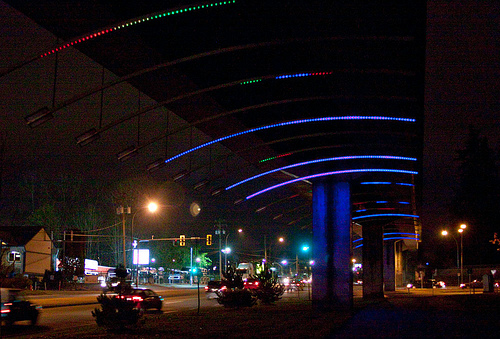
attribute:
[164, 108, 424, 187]
light — neon, street, blue, traffic, multicolored, post, shining, tail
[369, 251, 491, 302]
yard — building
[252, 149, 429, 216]
pole — electric, telephone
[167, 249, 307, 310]
car — going, moving, driving, approaching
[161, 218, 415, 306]
street — barrier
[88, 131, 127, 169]
night — black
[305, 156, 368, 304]
pillar — concrete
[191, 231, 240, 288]
traffic — electric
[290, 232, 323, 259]
signal — traffic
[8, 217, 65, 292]
house — small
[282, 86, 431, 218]
archway — lit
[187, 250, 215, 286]
light — stop